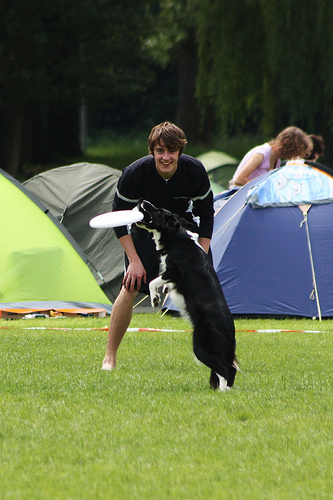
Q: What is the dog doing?
A: Catching a frisbee.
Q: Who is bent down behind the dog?
A: A boy in black.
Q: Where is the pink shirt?
A: On the curly haired woman.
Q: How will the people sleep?
A: In the tents.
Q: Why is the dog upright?
A: Jumping.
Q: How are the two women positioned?
A: Bent forward.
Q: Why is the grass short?
A: Cut.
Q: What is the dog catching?
A: Frisbee.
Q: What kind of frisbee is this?
A: White and round.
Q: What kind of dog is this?
A: Black and white dog.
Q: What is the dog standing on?
A: Hind legs.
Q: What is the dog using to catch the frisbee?
A: Teeth and mouth.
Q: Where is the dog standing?
A: Grass.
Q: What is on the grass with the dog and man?
A: Tents.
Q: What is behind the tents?
A: Green trees.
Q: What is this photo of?
A: A park.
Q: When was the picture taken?
A: Daytime.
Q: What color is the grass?
A: Green.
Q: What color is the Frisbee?
A: White.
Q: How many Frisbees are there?
A: One.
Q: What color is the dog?
A: Black and white.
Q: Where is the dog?
A: On the grass.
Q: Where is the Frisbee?
A: In the dog's mouth.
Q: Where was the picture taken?
A: At a campground.